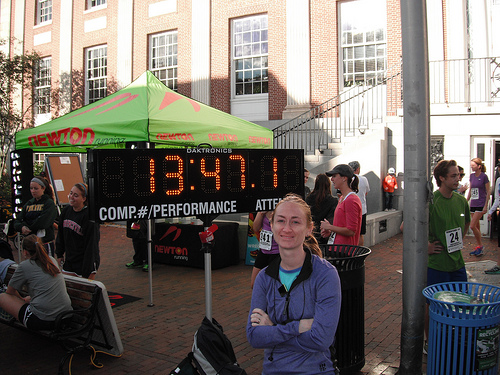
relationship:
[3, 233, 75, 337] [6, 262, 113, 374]
lady on bench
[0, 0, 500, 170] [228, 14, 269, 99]
building has window